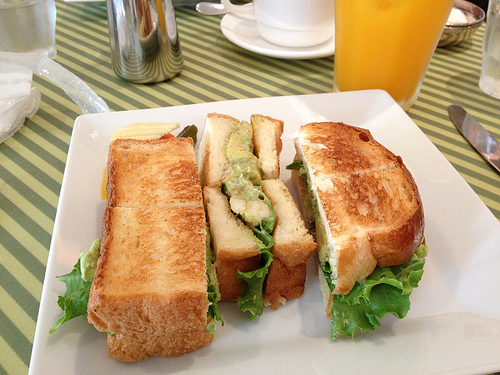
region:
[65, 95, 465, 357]
a plate full of food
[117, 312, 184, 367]
the crust of some bread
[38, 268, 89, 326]
a piece of some lettuce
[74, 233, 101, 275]
a piece of iceburg lettuce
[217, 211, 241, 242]
the white on some bread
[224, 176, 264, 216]
a piece of some chicken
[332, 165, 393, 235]
the toasted part of some bread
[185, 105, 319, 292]
a third of a sandwhich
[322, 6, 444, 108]
a glass of some orange juice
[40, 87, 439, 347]
sandwich portions on plate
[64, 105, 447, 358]
nice sandwich portions on plate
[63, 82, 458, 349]
three sandwich portions on plate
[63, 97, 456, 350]
great sandwich portions on plate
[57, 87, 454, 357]
tasty sandwich portions on plate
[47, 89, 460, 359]
flavorful sandwich portions on plate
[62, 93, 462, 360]
seasoned sandwich portions on plate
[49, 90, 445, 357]
thick sandwich portions on plate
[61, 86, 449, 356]
delicious sandwich portions on plate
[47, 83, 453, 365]
sandwich portions on white plate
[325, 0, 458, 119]
glass of orange juice on table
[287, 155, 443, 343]
lettuce on sandwich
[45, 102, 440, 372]
toasted sandwich cut in three pieces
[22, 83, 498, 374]
white square plate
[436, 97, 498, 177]
silver butter knife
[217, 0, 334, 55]
white coffee cup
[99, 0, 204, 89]
silver cup on table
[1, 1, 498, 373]
striped green table cloth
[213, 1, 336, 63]
small white plate under coffee cup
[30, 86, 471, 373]
a plate full of a meal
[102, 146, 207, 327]
the top piece of bread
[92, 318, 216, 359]
the bottom piece of bread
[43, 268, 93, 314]
a piece of romaine lettuce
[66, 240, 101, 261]
a piece of iceberg lettuce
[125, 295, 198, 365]
the crust of a sandwhich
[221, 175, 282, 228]
a large piece of chicken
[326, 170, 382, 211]
the toasted part of the bread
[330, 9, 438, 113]
a tall glass of orange juice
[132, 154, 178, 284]
Toasted bread on a plate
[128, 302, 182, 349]
A sandwich of toasted bread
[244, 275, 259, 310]
Lettuce in the sandwich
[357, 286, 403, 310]
A lettuce piece sticking out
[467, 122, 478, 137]
A knife on the table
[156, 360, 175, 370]
Shadow of toast on plate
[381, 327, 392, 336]
Lettuce casting shadow on plate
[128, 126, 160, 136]
A piece of corn